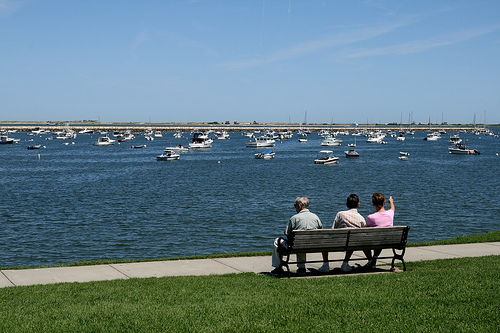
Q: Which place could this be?
A: It is an ocean.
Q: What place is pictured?
A: It is an ocean.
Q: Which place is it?
A: It is an ocean.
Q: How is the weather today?
A: It is cloudless.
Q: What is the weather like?
A: It is cloudless.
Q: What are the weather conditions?
A: It is cloudless.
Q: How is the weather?
A: It is cloudless.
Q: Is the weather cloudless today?
A: Yes, it is cloudless.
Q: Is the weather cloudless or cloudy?
A: It is cloudless.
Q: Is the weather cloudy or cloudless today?
A: It is cloudless.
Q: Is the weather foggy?
A: No, it is cloudless.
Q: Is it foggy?
A: No, it is cloudless.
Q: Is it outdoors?
A: Yes, it is outdoors.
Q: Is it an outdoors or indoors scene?
A: It is outdoors.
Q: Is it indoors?
A: No, it is outdoors.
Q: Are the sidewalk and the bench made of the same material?
A: No, the sidewalk is made of concrete and the bench is made of wood.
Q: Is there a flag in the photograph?
A: No, there are no flags.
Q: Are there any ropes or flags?
A: No, there are no flags or ropes.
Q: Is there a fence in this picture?
A: No, there are no fences.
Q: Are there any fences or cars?
A: No, there are no fences or cars.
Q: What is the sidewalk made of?
A: The sidewalk is made of concrete.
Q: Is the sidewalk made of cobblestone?
A: No, the sidewalk is made of concrete.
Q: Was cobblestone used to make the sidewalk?
A: No, the sidewalk is made of concrete.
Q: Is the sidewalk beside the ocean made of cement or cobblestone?
A: The sidewalk is made of cement.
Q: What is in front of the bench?
A: The sidewalk is in front of the bench.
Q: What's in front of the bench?
A: The sidewalk is in front of the bench.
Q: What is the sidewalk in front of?
A: The sidewalk is in front of the bench.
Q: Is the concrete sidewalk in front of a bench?
A: Yes, the sidewalk is in front of a bench.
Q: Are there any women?
A: Yes, there is a woman.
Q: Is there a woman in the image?
A: Yes, there is a woman.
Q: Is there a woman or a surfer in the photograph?
A: Yes, there is a woman.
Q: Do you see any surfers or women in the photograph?
A: Yes, there is a woman.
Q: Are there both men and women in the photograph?
A: Yes, there are both a woman and a man.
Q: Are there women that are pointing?
A: Yes, there is a woman that is pointing.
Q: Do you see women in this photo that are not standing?
A: Yes, there is a woman that is pointing .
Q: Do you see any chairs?
A: No, there are no chairs.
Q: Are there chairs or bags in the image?
A: No, there are no chairs or bags.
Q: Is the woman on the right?
A: Yes, the woman is on the right of the image.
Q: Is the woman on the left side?
A: No, the woman is on the right of the image.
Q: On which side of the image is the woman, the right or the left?
A: The woman is on the right of the image.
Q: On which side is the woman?
A: The woman is on the right of the image.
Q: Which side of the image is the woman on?
A: The woman is on the right of the image.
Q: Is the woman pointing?
A: Yes, the woman is pointing.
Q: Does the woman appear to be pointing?
A: Yes, the woman is pointing.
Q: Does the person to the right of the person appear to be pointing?
A: Yes, the woman is pointing.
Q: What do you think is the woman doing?
A: The woman is pointing.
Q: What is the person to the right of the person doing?
A: The woman is pointing.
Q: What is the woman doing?
A: The woman is pointing.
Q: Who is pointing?
A: The woman is pointing.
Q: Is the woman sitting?
A: No, the woman is pointing.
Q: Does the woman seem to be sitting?
A: No, the woman is pointing.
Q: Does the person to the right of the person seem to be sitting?
A: No, the woman is pointing.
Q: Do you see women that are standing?
A: No, there is a woman but she is pointing.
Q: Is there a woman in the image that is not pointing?
A: No, there is a woman but she is pointing.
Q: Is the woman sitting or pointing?
A: The woman is pointing.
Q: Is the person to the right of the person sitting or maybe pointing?
A: The woman is pointing.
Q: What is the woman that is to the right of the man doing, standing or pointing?
A: The woman is pointing.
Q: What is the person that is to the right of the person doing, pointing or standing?
A: The woman is pointing.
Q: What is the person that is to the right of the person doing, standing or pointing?
A: The woman is pointing.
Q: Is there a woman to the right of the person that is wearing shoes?
A: Yes, there is a woman to the right of the person.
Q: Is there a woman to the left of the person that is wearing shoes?
A: No, the woman is to the right of the person.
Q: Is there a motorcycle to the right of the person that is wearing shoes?
A: No, there is a woman to the right of the person.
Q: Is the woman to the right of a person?
A: Yes, the woman is to the right of a person.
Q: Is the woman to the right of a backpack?
A: No, the woman is to the right of a person.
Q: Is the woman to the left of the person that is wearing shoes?
A: No, the woman is to the right of the person.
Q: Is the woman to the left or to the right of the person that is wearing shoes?
A: The woman is to the right of the person.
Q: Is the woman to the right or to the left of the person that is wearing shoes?
A: The woman is to the right of the person.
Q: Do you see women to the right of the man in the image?
A: Yes, there is a woman to the right of the man.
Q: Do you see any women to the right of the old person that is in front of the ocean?
A: Yes, there is a woman to the right of the man.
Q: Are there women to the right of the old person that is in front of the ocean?
A: Yes, there is a woman to the right of the man.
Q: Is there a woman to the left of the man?
A: No, the woman is to the right of the man.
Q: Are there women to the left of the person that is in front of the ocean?
A: No, the woman is to the right of the man.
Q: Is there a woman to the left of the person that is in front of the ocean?
A: No, the woman is to the right of the man.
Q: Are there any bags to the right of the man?
A: No, there is a woman to the right of the man.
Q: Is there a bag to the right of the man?
A: No, there is a woman to the right of the man.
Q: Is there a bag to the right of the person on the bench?
A: No, there is a woman to the right of the man.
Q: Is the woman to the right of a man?
A: Yes, the woman is to the right of a man.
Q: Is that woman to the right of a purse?
A: No, the woman is to the right of a man.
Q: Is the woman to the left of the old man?
A: No, the woman is to the right of the man.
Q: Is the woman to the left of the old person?
A: No, the woman is to the right of the man.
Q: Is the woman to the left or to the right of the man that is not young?
A: The woman is to the right of the man.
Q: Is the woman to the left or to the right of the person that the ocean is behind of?
A: The woman is to the right of the man.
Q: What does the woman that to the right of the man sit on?
A: The woman sits on the bench.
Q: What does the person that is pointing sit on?
A: The woman sits on the bench.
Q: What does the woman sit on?
A: The woman sits on the bench.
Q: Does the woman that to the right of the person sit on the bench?
A: Yes, the woman sits on the bench.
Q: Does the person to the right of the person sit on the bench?
A: Yes, the woman sits on the bench.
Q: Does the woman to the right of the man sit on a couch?
A: No, the woman sits on the bench.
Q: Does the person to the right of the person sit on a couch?
A: No, the woman sits on the bench.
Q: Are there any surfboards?
A: No, there are no surfboards.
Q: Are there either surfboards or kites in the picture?
A: No, there are no surfboards or kites.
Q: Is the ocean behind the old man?
A: Yes, the ocean is behind the man.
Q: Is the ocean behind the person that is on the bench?
A: Yes, the ocean is behind the man.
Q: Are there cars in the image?
A: No, there are no cars.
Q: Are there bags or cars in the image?
A: No, there are no cars or bags.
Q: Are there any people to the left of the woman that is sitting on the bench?
A: Yes, there is a person to the left of the woman.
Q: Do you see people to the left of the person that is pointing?
A: Yes, there is a person to the left of the woman.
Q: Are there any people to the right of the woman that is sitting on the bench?
A: No, the person is to the left of the woman.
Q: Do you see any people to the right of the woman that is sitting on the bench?
A: No, the person is to the left of the woman.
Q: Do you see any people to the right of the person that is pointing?
A: No, the person is to the left of the woman.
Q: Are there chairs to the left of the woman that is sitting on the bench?
A: No, there is a person to the left of the woman.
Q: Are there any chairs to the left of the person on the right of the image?
A: No, there is a person to the left of the woman.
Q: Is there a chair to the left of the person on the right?
A: No, there is a person to the left of the woman.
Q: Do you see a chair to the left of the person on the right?
A: No, there is a person to the left of the woman.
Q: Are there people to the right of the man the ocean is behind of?
A: Yes, there is a person to the right of the man.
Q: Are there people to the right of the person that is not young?
A: Yes, there is a person to the right of the man.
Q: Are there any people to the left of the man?
A: No, the person is to the right of the man.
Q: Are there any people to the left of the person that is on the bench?
A: No, the person is to the right of the man.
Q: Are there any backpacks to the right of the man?
A: No, there is a person to the right of the man.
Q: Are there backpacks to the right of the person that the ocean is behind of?
A: No, there is a person to the right of the man.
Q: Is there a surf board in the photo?
A: No, there are no surfboards.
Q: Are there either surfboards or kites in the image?
A: No, there are no surfboards or kites.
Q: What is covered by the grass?
A: The shore is covered by the grass.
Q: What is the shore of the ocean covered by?
A: The shore is covered by the grass.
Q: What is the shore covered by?
A: The shore is covered by the grass.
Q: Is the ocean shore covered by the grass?
A: Yes, the shore is covered by the grass.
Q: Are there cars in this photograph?
A: No, there are no cars.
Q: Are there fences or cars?
A: No, there are no cars or fences.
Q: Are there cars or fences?
A: No, there are no cars or fences.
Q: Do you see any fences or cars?
A: No, there are no cars or fences.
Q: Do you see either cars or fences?
A: No, there are no cars or fences.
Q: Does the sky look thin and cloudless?
A: Yes, the sky is thin and cloudless.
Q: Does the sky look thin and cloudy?
A: No, the sky is thin but cloudless.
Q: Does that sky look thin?
A: Yes, the sky is thin.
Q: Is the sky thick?
A: No, the sky is thin.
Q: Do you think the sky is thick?
A: No, the sky is thin.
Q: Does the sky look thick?
A: No, the sky is thin.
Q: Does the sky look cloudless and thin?
A: Yes, the sky is cloudless and thin.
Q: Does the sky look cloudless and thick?
A: No, the sky is cloudless but thin.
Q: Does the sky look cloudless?
A: Yes, the sky is cloudless.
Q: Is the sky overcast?
A: No, the sky is cloudless.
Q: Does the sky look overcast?
A: No, the sky is cloudless.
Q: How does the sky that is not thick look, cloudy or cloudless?
A: The sky is cloudless.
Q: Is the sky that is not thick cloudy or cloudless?
A: The sky is cloudless.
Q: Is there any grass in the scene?
A: Yes, there is grass.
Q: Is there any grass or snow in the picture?
A: Yes, there is grass.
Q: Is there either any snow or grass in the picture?
A: Yes, there is grass.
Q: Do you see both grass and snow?
A: No, there is grass but no snow.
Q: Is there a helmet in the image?
A: No, there are no helmets.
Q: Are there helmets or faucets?
A: No, there are no helmets or faucets.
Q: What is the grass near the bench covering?
A: The grass is covering the shore.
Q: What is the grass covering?
A: The grass is covering the shore.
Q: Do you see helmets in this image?
A: No, there are no helmets.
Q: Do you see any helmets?
A: No, there are no helmets.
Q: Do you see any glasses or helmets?
A: No, there are no helmets or glasses.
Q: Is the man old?
A: Yes, the man is old.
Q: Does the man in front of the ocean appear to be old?
A: Yes, the man is old.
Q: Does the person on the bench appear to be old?
A: Yes, the man is old.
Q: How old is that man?
A: The man is old.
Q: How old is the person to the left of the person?
A: The man is old.